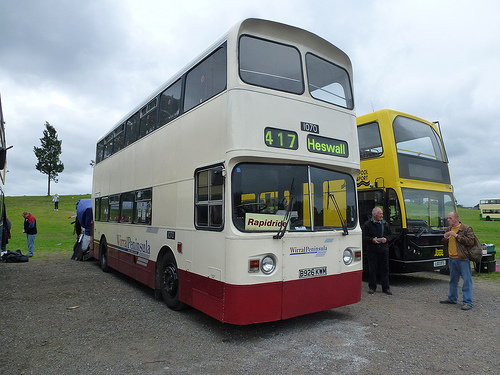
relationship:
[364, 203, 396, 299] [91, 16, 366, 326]
man near bus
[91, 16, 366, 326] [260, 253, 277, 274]
bus has light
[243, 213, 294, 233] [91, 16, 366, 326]
sign mounted on bus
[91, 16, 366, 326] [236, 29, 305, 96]
bus has window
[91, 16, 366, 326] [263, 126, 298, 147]
bus has number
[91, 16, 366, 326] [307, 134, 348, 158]
bus has destination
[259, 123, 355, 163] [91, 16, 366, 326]
display on top of bus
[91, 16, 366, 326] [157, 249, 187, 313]
bus has wheel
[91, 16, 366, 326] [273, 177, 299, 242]
bus has wiper